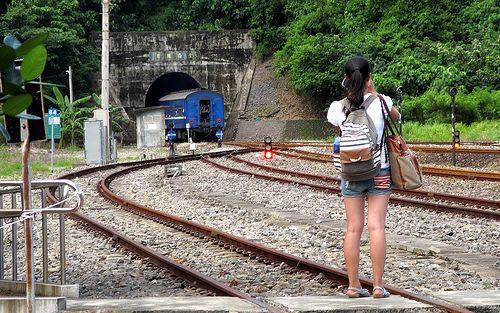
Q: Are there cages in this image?
A: No, there are no cages.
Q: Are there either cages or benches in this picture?
A: No, there are no cages or benches.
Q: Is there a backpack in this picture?
A: Yes, there is a backpack.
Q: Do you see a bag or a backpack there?
A: Yes, there is a backpack.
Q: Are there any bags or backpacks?
A: Yes, there is a backpack.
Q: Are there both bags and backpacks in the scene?
A: Yes, there are both a backpack and a bag.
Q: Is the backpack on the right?
A: Yes, the backpack is on the right of the image.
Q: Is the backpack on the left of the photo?
A: No, the backpack is on the right of the image.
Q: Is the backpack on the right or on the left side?
A: The backpack is on the right of the image.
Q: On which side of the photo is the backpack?
A: The backpack is on the right of the image.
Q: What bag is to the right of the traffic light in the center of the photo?
A: The bag is a backpack.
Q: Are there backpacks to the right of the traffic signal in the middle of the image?
A: Yes, there is a backpack to the right of the signal light.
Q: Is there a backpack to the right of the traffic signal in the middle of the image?
A: Yes, there is a backpack to the right of the signal light.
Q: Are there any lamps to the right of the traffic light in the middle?
A: No, there is a backpack to the right of the traffic light.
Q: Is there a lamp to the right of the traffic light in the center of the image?
A: No, there is a backpack to the right of the traffic light.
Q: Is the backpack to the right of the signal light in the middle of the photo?
A: Yes, the backpack is to the right of the traffic light.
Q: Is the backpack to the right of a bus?
A: No, the backpack is to the right of the traffic light.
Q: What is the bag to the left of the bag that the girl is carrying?
A: The bag is a backpack.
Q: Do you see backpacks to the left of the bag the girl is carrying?
A: Yes, there is a backpack to the left of the bag.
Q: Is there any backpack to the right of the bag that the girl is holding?
A: No, the backpack is to the left of the bag.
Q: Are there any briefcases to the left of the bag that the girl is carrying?
A: No, there is a backpack to the left of the bag.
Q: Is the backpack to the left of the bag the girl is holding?
A: Yes, the backpack is to the left of the bag.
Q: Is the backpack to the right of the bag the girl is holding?
A: No, the backpack is to the left of the bag.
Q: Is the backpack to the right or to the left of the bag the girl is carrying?
A: The backpack is to the left of the bag.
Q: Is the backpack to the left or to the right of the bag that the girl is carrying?
A: The backpack is to the left of the bag.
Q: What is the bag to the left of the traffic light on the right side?
A: The bag is a backpack.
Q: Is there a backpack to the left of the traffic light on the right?
A: Yes, there is a backpack to the left of the signal light.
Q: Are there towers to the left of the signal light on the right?
A: No, there is a backpack to the left of the traffic light.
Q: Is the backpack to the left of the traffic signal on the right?
A: Yes, the backpack is to the left of the traffic light.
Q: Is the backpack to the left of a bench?
A: No, the backpack is to the left of the traffic light.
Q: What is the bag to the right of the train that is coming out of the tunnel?
A: The bag is a backpack.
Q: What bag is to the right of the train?
A: The bag is a backpack.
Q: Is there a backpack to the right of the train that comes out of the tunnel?
A: Yes, there is a backpack to the right of the train.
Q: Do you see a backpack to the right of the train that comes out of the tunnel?
A: Yes, there is a backpack to the right of the train.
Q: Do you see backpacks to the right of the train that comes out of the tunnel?
A: Yes, there is a backpack to the right of the train.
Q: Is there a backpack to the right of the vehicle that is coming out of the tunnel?
A: Yes, there is a backpack to the right of the train.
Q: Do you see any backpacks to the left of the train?
A: No, the backpack is to the right of the train.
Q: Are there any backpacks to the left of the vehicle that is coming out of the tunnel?
A: No, the backpack is to the right of the train.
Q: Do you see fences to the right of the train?
A: No, there is a backpack to the right of the train.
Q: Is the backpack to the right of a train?
A: Yes, the backpack is to the right of a train.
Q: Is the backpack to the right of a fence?
A: No, the backpack is to the right of a train.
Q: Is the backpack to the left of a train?
A: No, the backpack is to the right of a train.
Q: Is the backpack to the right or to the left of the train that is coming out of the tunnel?
A: The backpack is to the right of the train.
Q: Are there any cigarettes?
A: No, there are no cigarettes.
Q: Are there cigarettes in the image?
A: No, there are no cigarettes.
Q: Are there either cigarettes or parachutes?
A: No, there are no cigarettes or parachutes.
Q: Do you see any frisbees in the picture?
A: No, there are no frisbees.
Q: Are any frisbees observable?
A: No, there are no frisbees.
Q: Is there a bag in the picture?
A: Yes, there is a bag.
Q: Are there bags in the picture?
A: Yes, there is a bag.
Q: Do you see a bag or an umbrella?
A: Yes, there is a bag.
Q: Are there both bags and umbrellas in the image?
A: No, there is a bag but no umbrellas.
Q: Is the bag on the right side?
A: Yes, the bag is on the right of the image.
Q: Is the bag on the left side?
A: No, the bag is on the right of the image.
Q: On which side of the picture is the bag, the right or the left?
A: The bag is on the right of the image.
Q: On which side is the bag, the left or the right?
A: The bag is on the right of the image.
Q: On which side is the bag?
A: The bag is on the right of the image.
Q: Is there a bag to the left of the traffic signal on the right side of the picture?
A: Yes, there is a bag to the left of the signal light.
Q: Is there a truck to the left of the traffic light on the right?
A: No, there is a bag to the left of the traffic signal.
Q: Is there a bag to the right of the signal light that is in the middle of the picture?
A: Yes, there is a bag to the right of the traffic signal.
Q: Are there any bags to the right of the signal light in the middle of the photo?
A: Yes, there is a bag to the right of the traffic signal.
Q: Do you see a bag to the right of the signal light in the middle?
A: Yes, there is a bag to the right of the traffic signal.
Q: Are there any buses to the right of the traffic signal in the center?
A: No, there is a bag to the right of the traffic light.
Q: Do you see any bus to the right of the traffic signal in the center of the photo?
A: No, there is a bag to the right of the traffic light.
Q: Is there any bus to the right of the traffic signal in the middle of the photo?
A: No, there is a bag to the right of the traffic light.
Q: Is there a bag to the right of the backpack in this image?
A: Yes, there is a bag to the right of the backpack.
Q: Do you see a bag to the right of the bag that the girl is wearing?
A: Yes, there is a bag to the right of the backpack.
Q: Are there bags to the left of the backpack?
A: No, the bag is to the right of the backpack.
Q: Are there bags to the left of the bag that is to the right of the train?
A: No, the bag is to the right of the backpack.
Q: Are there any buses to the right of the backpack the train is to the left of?
A: No, there is a bag to the right of the backpack.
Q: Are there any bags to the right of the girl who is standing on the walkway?
A: Yes, there is a bag to the right of the girl.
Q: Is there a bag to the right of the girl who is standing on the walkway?
A: Yes, there is a bag to the right of the girl.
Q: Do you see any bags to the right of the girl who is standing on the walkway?
A: Yes, there is a bag to the right of the girl.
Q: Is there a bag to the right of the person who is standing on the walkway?
A: Yes, there is a bag to the right of the girl.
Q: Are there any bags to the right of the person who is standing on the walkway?
A: Yes, there is a bag to the right of the girl.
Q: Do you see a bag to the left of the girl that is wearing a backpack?
A: No, the bag is to the right of the girl.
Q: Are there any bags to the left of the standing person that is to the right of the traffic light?
A: No, the bag is to the right of the girl.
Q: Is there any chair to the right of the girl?
A: No, there is a bag to the right of the girl.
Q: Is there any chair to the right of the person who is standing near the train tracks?
A: No, there is a bag to the right of the girl.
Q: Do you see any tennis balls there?
A: No, there are no tennis balls.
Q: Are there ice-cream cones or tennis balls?
A: No, there are no tennis balls or ice-cream cones.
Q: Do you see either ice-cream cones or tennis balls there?
A: No, there are no tennis balls or ice-cream cones.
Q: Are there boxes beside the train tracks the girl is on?
A: Yes, there is a box beside the train tracks.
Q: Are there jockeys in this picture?
A: No, there are no jockeys.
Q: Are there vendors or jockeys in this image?
A: No, there are no jockeys or vendors.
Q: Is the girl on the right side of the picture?
A: Yes, the girl is on the right of the image.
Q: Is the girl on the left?
A: No, the girl is on the right of the image.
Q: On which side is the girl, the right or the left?
A: The girl is on the right of the image.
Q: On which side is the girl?
A: The girl is on the right of the image.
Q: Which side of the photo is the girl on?
A: The girl is on the right of the image.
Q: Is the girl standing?
A: Yes, the girl is standing.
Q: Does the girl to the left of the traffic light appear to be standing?
A: Yes, the girl is standing.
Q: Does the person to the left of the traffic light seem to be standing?
A: Yes, the girl is standing.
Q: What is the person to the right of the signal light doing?
A: The girl is standing.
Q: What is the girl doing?
A: The girl is standing.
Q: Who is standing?
A: The girl is standing.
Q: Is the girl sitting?
A: No, the girl is standing.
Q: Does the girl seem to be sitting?
A: No, the girl is standing.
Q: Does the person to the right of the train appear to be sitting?
A: No, the girl is standing.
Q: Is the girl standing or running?
A: The girl is standing.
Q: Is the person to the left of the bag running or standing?
A: The girl is standing.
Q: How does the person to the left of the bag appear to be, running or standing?
A: The girl is standing.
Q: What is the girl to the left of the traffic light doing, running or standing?
A: The girl is standing.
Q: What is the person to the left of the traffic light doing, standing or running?
A: The girl is standing.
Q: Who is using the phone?
A: The girl is using the phone.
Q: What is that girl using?
A: The girl is using a telephone.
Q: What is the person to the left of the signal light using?
A: The girl is using a telephone.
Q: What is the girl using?
A: The girl is using a telephone.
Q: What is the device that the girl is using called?
A: The device is a phone.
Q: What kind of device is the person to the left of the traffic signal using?
A: The girl is using a telephone.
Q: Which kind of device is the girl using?
A: The girl is using a telephone.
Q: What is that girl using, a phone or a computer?
A: The girl is using a phone.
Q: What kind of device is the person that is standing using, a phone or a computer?
A: The girl is using a phone.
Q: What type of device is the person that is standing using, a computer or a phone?
A: The girl is using a phone.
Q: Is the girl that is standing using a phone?
A: Yes, the girl is using a phone.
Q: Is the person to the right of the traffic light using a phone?
A: Yes, the girl is using a phone.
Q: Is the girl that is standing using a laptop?
A: No, the girl is using a phone.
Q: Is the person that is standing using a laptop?
A: No, the girl is using a phone.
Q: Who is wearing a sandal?
A: The girl is wearing a sandal.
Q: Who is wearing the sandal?
A: The girl is wearing a sandal.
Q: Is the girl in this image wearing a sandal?
A: Yes, the girl is wearing a sandal.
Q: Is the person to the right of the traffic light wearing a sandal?
A: Yes, the girl is wearing a sandal.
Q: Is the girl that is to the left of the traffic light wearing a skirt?
A: No, the girl is wearing a sandal.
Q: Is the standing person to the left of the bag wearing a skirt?
A: No, the girl is wearing a sandal.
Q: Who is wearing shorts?
A: The girl is wearing shorts.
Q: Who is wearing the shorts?
A: The girl is wearing shorts.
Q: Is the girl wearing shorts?
A: Yes, the girl is wearing shorts.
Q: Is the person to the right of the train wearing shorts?
A: Yes, the girl is wearing shorts.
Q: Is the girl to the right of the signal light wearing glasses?
A: No, the girl is wearing shorts.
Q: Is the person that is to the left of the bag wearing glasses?
A: No, the girl is wearing shorts.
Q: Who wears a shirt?
A: The girl wears a shirt.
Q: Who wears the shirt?
A: The girl wears a shirt.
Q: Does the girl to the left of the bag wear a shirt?
A: Yes, the girl wears a shirt.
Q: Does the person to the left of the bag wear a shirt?
A: Yes, the girl wears a shirt.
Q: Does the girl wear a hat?
A: No, the girl wears a shirt.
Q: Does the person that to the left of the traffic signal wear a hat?
A: No, the girl wears a shirt.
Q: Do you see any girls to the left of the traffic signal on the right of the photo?
A: Yes, there is a girl to the left of the traffic light.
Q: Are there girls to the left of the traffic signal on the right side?
A: Yes, there is a girl to the left of the traffic light.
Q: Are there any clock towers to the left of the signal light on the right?
A: No, there is a girl to the left of the traffic signal.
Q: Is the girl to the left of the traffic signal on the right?
A: Yes, the girl is to the left of the traffic light.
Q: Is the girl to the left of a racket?
A: No, the girl is to the left of the traffic light.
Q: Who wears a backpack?
A: The girl wears a backpack.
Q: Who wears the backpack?
A: The girl wears a backpack.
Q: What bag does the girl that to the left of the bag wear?
A: The girl wears a backpack.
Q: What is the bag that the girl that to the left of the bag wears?
A: The bag is a backpack.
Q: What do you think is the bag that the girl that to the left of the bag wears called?
A: The bag is a backpack.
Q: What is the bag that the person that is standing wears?
A: The bag is a backpack.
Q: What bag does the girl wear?
A: The girl wears a backpack.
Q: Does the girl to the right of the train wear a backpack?
A: Yes, the girl wears a backpack.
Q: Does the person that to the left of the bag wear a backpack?
A: Yes, the girl wears a backpack.